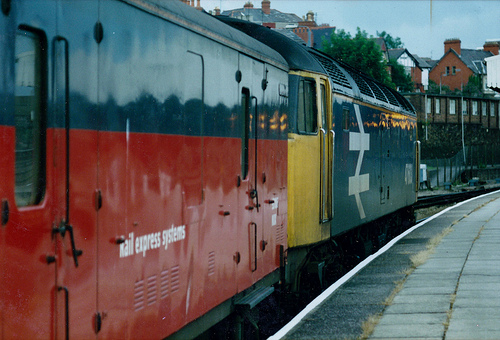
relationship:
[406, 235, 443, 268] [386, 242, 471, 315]
dead grass growing between paving stones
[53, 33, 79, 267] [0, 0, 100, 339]
hand rail near access door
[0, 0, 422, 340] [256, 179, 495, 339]
locomotive on tracks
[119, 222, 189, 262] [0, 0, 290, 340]
white words on car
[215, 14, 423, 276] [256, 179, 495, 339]
car on tracks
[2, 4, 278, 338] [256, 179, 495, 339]
car on tracks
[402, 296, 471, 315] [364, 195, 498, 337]
paving stones in path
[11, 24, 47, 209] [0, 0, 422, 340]
window in locomotive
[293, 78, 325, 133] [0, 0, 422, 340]
window in locomotive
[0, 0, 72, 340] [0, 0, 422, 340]
access door of locomotive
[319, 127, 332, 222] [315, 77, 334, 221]
rail of door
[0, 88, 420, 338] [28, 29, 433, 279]
reflection on side train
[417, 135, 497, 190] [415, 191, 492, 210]
fence running along track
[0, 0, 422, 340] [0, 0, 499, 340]
locomotive parked in station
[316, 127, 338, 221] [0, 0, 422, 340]
handle of locomotive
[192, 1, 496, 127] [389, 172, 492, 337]
buildings near station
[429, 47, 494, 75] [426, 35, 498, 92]
house roof of building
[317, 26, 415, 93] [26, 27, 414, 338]
green trees behind train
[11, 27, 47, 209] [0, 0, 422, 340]
window of locomotive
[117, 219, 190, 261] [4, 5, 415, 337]
name of locomotive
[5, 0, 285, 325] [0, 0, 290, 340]
side of car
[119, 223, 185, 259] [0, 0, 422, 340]
logo on locomotive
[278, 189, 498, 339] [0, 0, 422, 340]
pavement blocks near locomotive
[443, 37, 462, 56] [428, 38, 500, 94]
chimney near building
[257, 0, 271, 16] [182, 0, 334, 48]
chimney near buildings